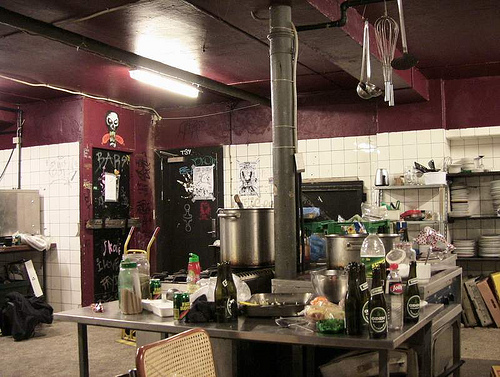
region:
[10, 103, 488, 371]
dirty kitchen with grafitti on doors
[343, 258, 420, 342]
several green beer bottles on counter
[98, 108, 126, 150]
skull on the ceiling above the door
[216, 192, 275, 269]
large silver stew pot on burner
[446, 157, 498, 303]
metal shelf with stacks of plates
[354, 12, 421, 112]
ladels and whisk hanging from ceiling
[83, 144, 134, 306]
black door with grafitti on it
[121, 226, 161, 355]
empty yellow cart with red handles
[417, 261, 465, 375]
silver oven with black knobs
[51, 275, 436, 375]
silver countertop littered with garbage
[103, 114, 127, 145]
an allien figure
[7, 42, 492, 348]
a restaurant kitchen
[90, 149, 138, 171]
graffiti on the door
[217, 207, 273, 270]
a very large soup pot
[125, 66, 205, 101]
a brilliant white light lamp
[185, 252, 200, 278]
a ketchup bottle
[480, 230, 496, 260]
a stack of plates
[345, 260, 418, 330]
several bottles of wine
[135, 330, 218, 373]
top of the chair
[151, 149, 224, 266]
a black door with many signs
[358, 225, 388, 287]
Plastic bottle with green lid and label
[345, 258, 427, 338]
Several dark glassed beer bottles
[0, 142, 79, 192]
White tiled wall in the background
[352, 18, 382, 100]
Large metallic cooking ladles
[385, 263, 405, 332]
Plastic bottle with red cap and label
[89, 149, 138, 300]
Black door covered in graffiti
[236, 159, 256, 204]
Small poster on tiled wall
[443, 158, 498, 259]
Stack of dishes on dish tower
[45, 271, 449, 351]
Metal table covered with cooking materials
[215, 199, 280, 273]
Large metal pot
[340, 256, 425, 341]
bottles on a stainless steel table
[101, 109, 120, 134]
skull on a red wall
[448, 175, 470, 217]
bowls on a shelf in a kitchen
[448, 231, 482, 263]
plates on a shelf in a kitchen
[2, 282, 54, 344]
black backpack on a floor in a kitchen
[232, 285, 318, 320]
fry pan on a stainless steel table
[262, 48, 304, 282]
tall gray exhaust pipe in a kitchen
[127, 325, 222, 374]
back of a chair in a kitchen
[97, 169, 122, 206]
white paper taped on a black door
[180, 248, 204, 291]
red plastic bottle with green screw top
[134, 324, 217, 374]
back of a rattan chair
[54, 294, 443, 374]
cluttered steel table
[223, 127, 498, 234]
white tiles on wall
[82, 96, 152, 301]
skull painted on purple wall above black door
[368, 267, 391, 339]
beer bottle on steel table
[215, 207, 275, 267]
large metal cooking pot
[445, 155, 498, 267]
shelves with stacked plates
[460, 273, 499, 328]
vertical pizza boxes on floor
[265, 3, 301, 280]
exhaust pipe behind steel table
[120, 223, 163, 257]
handles of dolly